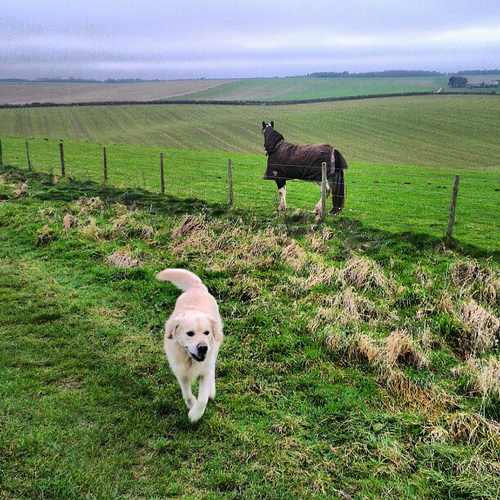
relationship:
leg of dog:
[174, 377, 197, 407] [153, 266, 225, 422]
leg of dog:
[186, 373, 213, 421] [153, 266, 225, 422]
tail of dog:
[153, 267, 205, 286] [153, 266, 225, 422]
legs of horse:
[270, 169, 287, 211] [257, 120, 349, 217]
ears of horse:
[257, 112, 274, 130] [234, 122, 355, 233]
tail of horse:
[318, 153, 366, 203] [253, 113, 355, 219]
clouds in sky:
[21, 13, 496, 65] [6, 5, 493, 77]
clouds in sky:
[0, 26, 500, 53] [114, 9, 239, 79]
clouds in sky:
[0, 26, 500, 53] [6, 3, 490, 67]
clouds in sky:
[0, 26, 500, 53] [2, 2, 486, 85]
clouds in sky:
[0, 26, 500, 53] [119, 9, 237, 49]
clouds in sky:
[0, 26, 500, 53] [2, 3, 490, 56]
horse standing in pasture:
[257, 120, 349, 217] [347, 159, 489, 232]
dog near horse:
[153, 266, 225, 422] [257, 120, 349, 217]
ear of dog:
[161, 312, 183, 339] [153, 266, 225, 422]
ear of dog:
[208, 317, 221, 342] [153, 266, 225, 422]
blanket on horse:
[273, 138, 338, 178] [245, 113, 367, 203]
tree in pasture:
[446, 72, 474, 94] [12, 74, 492, 239]